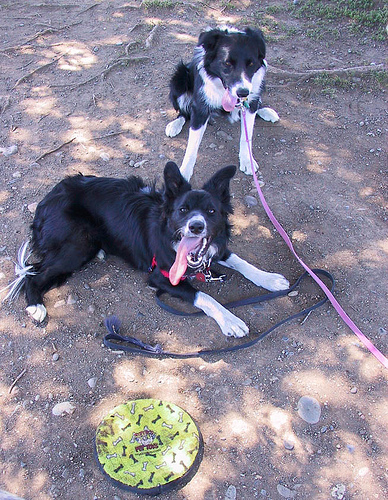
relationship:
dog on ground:
[1, 161, 290, 339] [291, 133, 387, 252]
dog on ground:
[1, 161, 290, 339] [1, 0, 387, 498]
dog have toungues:
[1, 161, 290, 339] [168, 82, 240, 283]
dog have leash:
[1, 161, 290, 339] [233, 163, 378, 318]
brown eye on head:
[223, 60, 232, 69] [199, 24, 272, 108]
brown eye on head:
[246, 61, 254, 68] [199, 24, 272, 108]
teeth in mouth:
[188, 237, 209, 266] [173, 231, 210, 269]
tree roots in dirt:
[105, 18, 158, 71] [1, 1, 387, 433]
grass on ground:
[197, 2, 384, 94] [1, 0, 387, 498]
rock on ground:
[52, 401, 77, 416] [275, 483, 297, 495]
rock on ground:
[297, 394, 321, 423] [275, 483, 297, 495]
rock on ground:
[222, 485, 241, 498] [275, 483, 297, 495]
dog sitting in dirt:
[1, 161, 290, 339] [1, 0, 387, 498]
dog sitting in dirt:
[164, 21, 279, 182] [1, 0, 387, 498]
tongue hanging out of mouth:
[165, 236, 202, 286] [176, 225, 208, 266]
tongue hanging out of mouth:
[220, 87, 236, 115] [221, 77, 248, 108]